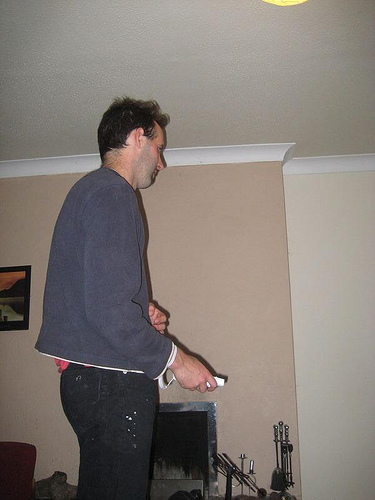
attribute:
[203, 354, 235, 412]
controller — white, wii, nintendo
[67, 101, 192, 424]
man — standing, playing, tall, close, visable, average, looking, watching, younger, white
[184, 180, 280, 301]
wall — brown, beige, colored, close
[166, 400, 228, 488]
fireplace — black, empty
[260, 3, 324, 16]
light — on, yellow, close, above